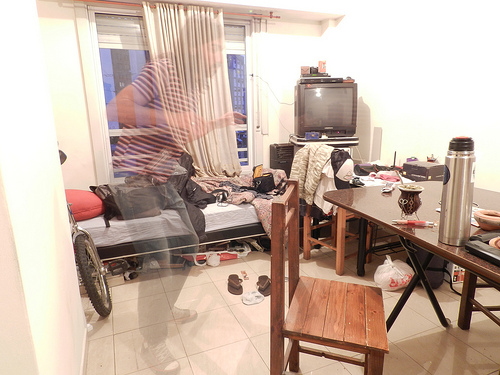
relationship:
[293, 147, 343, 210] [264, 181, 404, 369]
clothing thrown over back of a chair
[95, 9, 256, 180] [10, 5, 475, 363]
window in room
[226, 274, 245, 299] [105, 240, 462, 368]
brown flip-flop on floor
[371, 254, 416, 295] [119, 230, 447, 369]
plastic bag on floor